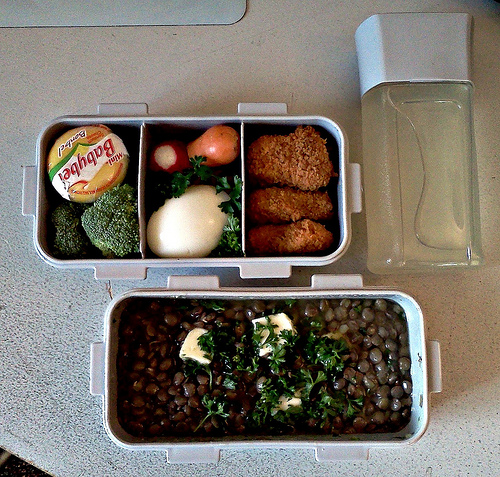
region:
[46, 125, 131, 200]
Round mini babybe cheese.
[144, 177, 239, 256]
Boiled egg surrounded by herbs.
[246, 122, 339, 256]
Three chicken nuggets in a tray.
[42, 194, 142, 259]
Two broccoli florets in a tray.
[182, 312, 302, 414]
Butter with herbs on it.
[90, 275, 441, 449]
Dish full of lento beans.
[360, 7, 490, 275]
Plastic water canister full of water.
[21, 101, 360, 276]
Tray of food with three sections.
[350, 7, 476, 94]
Cap of a water bottle.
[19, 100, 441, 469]
Two dishes of food.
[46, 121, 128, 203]
small round packaged cheese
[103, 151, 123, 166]
red print on a cheese package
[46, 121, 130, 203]
mini Babybel cheese in a container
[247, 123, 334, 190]
breaded meat in a gray container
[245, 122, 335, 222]
two pieces of breaded meat in a gray container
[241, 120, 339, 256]
three pieces of breaded meat in a gray container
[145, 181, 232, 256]
boiled egg in a gray container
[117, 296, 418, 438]
gray container of beans parsely and cheese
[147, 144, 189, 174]
piece of radish in a container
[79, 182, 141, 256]
brocolli in a gray container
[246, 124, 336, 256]
this looks like breaded chicken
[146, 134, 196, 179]
this is a reddish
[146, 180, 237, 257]
this seems to be mozzarella cheese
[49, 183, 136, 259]
raw broccoli is included with this meal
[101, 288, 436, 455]
a large serving of cooked beans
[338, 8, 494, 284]
this container holds water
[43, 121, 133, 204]
this cheese is still in its package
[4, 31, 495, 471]
the table surface looks like granite.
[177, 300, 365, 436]
parsley is used ad a garnish in the beans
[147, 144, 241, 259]
the mozzarella cheese is surrounded by parsley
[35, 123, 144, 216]
pack of babybel cheese in lunch box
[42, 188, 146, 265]
two broccoli crowns in lunch box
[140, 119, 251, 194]
two radishes in lunch box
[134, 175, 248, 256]
boiled egg in lunch box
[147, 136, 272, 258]
parsley in luncbox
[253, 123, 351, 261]
chicken nuggets in lunch box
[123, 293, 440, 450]
lentils in lunch box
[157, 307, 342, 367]
butter on lentils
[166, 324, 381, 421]
parsley over lentils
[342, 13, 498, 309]
bottle of water on table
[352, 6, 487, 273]
clear container of water laying on table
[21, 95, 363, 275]
container of food on table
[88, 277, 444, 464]
rectangular bowl filled with beans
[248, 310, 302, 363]
pat of butter and parsley in beans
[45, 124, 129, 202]
small round piece of cheese in package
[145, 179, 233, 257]
white oval hard boiled egg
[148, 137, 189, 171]
red radish with white center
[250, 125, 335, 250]
chunks of breaded meat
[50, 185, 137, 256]
two pieces of green broccoli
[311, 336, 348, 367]
chopped green pieces of parsley